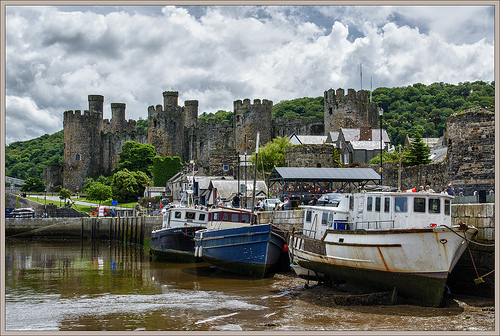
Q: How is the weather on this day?
A: It is cloudy.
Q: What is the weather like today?
A: It is cloudy.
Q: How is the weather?
A: It is cloudy.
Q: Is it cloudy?
A: Yes, it is cloudy.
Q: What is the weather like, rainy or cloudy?
A: It is cloudy.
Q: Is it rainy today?
A: No, it is cloudy.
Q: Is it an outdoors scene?
A: Yes, it is outdoors.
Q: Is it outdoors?
A: Yes, it is outdoors.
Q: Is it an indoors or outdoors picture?
A: It is outdoors.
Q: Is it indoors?
A: No, it is outdoors.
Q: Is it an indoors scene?
A: No, it is outdoors.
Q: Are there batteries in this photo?
A: No, there are no batteries.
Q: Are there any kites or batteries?
A: No, there are no batteries or kites.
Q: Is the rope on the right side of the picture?
A: Yes, the rope is on the right of the image.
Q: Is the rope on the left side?
A: No, the rope is on the right of the image.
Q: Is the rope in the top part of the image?
A: No, the rope is in the bottom of the image.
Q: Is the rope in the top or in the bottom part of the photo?
A: The rope is in the bottom of the image.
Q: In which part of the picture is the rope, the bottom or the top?
A: The rope is in the bottom of the image.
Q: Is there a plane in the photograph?
A: No, there are no airplanes.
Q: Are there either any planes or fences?
A: No, there are no planes or fences.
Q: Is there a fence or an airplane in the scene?
A: No, there are no airplanes or fences.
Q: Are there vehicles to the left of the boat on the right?
A: Yes, there is a vehicle to the left of the boat.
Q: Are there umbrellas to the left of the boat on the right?
A: No, there is a vehicle to the left of the boat.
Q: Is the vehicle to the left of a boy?
A: No, the vehicle is to the left of the boat.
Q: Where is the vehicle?
A: The vehicle is on the pier.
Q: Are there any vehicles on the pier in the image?
A: Yes, there is a vehicle on the pier.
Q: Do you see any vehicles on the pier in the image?
A: Yes, there is a vehicle on the pier.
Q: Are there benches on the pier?
A: No, there is a vehicle on the pier.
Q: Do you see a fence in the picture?
A: No, there are no fences.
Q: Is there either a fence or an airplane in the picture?
A: No, there are no fences or airplanes.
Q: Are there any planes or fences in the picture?
A: No, there are no fences or planes.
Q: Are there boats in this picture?
A: Yes, there is a boat.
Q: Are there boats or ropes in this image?
A: Yes, there is a boat.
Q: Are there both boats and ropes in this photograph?
A: Yes, there are both a boat and a rope.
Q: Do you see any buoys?
A: No, there are no buoys.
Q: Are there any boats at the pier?
A: Yes, there is a boat at the pier.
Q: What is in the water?
A: The boat is in the water.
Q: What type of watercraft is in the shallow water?
A: The watercraft is a boat.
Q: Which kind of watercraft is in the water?
A: The watercraft is a boat.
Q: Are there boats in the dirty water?
A: Yes, there is a boat in the water.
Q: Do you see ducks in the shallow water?
A: No, there is a boat in the water.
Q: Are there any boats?
A: Yes, there is a boat.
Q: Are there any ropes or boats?
A: Yes, there is a boat.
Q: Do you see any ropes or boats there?
A: Yes, there is a boat.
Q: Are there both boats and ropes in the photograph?
A: Yes, there are both a boat and a rope.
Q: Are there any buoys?
A: No, there are no buoys.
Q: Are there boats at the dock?
A: Yes, there is a boat at the dock.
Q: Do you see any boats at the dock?
A: Yes, there is a boat at the dock.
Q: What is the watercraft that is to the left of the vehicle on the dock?
A: The watercraft is a boat.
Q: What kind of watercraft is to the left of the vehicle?
A: The watercraft is a boat.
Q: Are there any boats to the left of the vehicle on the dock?
A: Yes, there is a boat to the left of the vehicle.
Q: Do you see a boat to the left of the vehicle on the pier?
A: Yes, there is a boat to the left of the vehicle.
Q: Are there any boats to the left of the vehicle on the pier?
A: Yes, there is a boat to the left of the vehicle.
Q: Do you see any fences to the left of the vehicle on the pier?
A: No, there is a boat to the left of the vehicle.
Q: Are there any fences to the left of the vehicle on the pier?
A: No, there is a boat to the left of the vehicle.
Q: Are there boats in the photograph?
A: Yes, there is a boat.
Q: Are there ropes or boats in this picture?
A: Yes, there is a boat.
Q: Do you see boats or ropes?
A: Yes, there is a boat.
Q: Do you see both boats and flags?
A: Yes, there are both a boat and a flag.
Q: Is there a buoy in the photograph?
A: No, there are no buoys.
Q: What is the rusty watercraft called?
A: The watercraft is a boat.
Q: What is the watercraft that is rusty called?
A: The watercraft is a boat.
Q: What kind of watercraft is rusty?
A: The watercraft is a boat.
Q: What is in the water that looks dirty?
A: The boat is in the water.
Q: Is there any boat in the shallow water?
A: Yes, there is a boat in the water.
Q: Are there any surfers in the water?
A: No, there is a boat in the water.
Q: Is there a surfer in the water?
A: No, there is a boat in the water.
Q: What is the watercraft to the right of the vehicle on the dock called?
A: The watercraft is a boat.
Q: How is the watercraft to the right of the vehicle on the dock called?
A: The watercraft is a boat.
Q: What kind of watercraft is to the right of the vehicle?
A: The watercraft is a boat.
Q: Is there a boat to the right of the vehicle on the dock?
A: Yes, there is a boat to the right of the vehicle.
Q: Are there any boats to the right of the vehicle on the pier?
A: Yes, there is a boat to the right of the vehicle.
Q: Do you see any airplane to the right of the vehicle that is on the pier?
A: No, there is a boat to the right of the vehicle.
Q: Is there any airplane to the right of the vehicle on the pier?
A: No, there is a boat to the right of the vehicle.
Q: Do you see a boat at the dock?
A: Yes, there is a boat at the dock.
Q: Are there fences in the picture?
A: No, there are no fences.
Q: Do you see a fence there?
A: No, there are no fences.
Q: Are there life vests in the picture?
A: No, there are no life vests.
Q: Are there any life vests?
A: No, there are no life vests.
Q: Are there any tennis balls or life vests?
A: No, there are no life vests or tennis balls.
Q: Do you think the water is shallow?
A: Yes, the water is shallow.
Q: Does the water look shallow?
A: Yes, the water is shallow.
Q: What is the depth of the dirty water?
A: The water is shallow.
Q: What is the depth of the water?
A: The water is shallow.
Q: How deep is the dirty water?
A: The water is shallow.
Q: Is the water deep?
A: No, the water is shallow.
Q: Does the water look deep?
A: No, the water is shallow.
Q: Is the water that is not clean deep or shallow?
A: The water is shallow.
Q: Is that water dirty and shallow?
A: Yes, the water is dirty and shallow.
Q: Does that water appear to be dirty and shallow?
A: Yes, the water is dirty and shallow.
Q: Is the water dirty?
A: Yes, the water is dirty.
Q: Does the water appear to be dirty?
A: Yes, the water is dirty.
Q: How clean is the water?
A: The water is dirty.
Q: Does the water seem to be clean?
A: No, the water is dirty.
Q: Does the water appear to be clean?
A: No, the water is dirty.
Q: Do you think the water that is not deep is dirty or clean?
A: The water is dirty.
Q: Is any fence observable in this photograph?
A: No, there are no fences.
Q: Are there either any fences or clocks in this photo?
A: No, there are no fences or clocks.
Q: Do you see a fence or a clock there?
A: No, there are no fences or clocks.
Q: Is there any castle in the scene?
A: Yes, there is a castle.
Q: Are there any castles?
A: Yes, there is a castle.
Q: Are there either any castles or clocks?
A: Yes, there is a castle.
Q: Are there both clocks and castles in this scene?
A: No, there is a castle but no clocks.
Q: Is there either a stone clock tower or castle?
A: Yes, there is a stone castle.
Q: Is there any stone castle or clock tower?
A: Yes, there is a stone castle.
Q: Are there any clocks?
A: No, there are no clocks.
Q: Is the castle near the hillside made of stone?
A: Yes, the castle is made of stone.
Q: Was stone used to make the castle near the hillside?
A: Yes, the castle is made of stone.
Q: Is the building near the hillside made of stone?
A: Yes, the castle is made of stone.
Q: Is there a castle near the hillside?
A: Yes, there is a castle near the hillside.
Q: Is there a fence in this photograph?
A: No, there are no fences.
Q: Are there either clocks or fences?
A: No, there are no fences or clocks.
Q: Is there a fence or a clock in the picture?
A: No, there are no fences or clocks.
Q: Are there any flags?
A: Yes, there is a flag.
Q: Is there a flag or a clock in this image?
A: Yes, there is a flag.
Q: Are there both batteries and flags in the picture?
A: No, there is a flag but no batteries.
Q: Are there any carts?
A: No, there are no carts.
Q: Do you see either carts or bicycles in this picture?
A: No, there are no carts or bicycles.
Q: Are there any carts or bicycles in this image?
A: No, there are no carts or bicycles.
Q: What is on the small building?
A: The flag is on the building.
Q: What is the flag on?
A: The flag is on the building.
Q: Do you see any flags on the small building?
A: Yes, there is a flag on the building.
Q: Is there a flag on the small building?
A: Yes, there is a flag on the building.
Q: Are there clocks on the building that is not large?
A: No, there is a flag on the building.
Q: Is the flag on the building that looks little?
A: Yes, the flag is on the building.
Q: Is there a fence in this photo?
A: No, there are no fences.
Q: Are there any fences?
A: No, there are no fences.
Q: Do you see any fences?
A: No, there are no fences.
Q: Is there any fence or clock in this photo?
A: No, there are no fences or clocks.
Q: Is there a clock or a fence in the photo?
A: No, there are no fences or clocks.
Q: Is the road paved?
A: Yes, the road is paved.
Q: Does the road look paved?
A: Yes, the road is paved.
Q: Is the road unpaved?
A: No, the road is paved.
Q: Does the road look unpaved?
A: No, the road is paved.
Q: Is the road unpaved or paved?
A: The road is paved.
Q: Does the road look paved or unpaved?
A: The road is paved.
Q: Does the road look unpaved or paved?
A: The road is paved.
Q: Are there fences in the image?
A: No, there are no fences.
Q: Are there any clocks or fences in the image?
A: No, there are no fences or clocks.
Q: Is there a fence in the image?
A: No, there are no fences.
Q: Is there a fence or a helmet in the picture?
A: No, there are no fences or helmets.